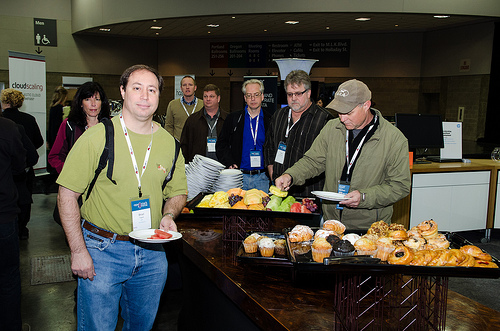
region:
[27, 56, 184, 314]
man wearing back pack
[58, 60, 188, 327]
man wearing green shirt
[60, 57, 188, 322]
man wearing blue jeans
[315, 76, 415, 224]
man wearing a cap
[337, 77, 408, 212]
man wearing a coat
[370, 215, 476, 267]
pastries on a table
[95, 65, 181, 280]
man holding a plate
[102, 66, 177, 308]
man wearing a badge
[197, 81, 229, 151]
man wearing a badge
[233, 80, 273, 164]
man wearing a blue shirt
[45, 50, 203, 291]
man wearing green shirt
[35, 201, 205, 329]
man wearing blue jeans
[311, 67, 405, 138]
man wearing khaki cap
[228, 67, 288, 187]
man wearing blue shirt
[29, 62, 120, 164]
lady wearing hot pink shirt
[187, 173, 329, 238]
fruit in tray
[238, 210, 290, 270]
muffins on tray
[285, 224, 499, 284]
pastries on tray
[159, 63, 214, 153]
man wearing green sweater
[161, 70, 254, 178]
man wearing black jacket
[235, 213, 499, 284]
pastries and muffins on trays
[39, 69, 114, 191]
lady wearing pink top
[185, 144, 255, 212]
stacked plates on table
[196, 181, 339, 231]
fruit in container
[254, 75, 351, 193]
man wearing black striped shirt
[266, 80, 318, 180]
man wearing glasses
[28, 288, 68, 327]
The ground is made of concrete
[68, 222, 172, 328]
The man is wearing blue jeans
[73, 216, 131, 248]
The man has on a brown belt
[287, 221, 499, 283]
The pastry on the tray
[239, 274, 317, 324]
The table is made of wood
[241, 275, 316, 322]
The color of the table is brown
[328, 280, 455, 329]
The crate on the table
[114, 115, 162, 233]
The man has on a badge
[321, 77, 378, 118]
The man has on a hat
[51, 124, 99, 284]
The arm on the man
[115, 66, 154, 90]
man has short hair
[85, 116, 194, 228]
man has green shirt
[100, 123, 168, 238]
man has white lanyard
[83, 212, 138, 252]
man has brown belt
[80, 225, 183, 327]
man has blue jeans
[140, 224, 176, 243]
man holds white plate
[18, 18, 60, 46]
black and white handicapped restroom sign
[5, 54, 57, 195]
white banner under bathroom sign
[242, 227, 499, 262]
large plate of pastries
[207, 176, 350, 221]
large plate of fruits